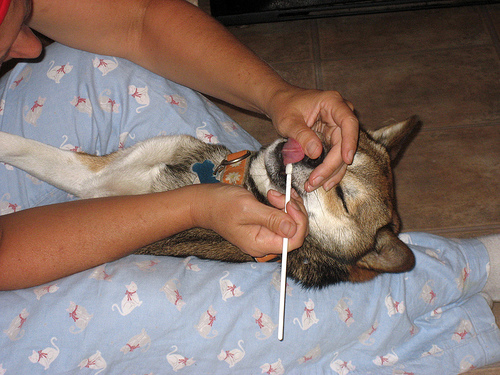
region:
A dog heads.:
[251, 94, 428, 314]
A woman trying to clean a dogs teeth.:
[267, 151, 297, 358]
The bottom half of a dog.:
[4, 128, 194, 205]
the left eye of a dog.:
[321, 170, 373, 238]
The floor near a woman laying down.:
[441, 127, 473, 177]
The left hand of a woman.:
[266, 81, 381, 206]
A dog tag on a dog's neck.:
[186, 126, 266, 208]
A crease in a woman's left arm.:
[121, 0, 174, 101]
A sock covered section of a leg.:
[481, 224, 497, 318]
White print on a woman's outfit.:
[381, 283, 421, 325]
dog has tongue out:
[280, 136, 305, 163]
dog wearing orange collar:
[220, 150, 277, 262]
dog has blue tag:
[190, 159, 215, 184]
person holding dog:
[0, 0, 499, 374]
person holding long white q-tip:
[277, 162, 293, 341]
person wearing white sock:
[476, 233, 498, 302]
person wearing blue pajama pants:
[0, 40, 498, 373]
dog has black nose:
[302, 145, 325, 167]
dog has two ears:
[356, 114, 416, 274]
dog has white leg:
[0, 129, 98, 195]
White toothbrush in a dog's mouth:
[273, 156, 293, 343]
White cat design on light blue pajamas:
[189, 299, 226, 348]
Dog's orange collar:
[221, 144, 253, 194]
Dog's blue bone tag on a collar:
[188, 156, 222, 191]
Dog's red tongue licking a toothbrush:
[280, 130, 311, 175]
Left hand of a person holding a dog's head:
[272, 60, 381, 195]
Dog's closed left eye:
[326, 162, 363, 222]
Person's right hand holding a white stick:
[211, 172, 310, 259]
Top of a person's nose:
[10, 24, 51, 68]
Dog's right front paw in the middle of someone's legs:
[0, 122, 110, 192]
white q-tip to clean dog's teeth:
[277, 158, 299, 358]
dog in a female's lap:
[9, 106, 449, 292]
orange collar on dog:
[214, 146, 253, 190]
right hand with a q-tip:
[210, 175, 320, 262]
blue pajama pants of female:
[88, 283, 275, 363]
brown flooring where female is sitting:
[344, 22, 485, 97]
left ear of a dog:
[356, 219, 418, 286]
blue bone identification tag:
[188, 158, 225, 190]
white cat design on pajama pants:
[111, 278, 148, 319]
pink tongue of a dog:
[281, 135, 308, 168]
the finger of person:
[247, 200, 296, 237]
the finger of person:
[287, 197, 304, 240]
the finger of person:
[269, 189, 299, 207]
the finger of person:
[290, 185, 307, 209]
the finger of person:
[286, 117, 321, 159]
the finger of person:
[329, 82, 359, 161]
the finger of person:
[309, 137, 339, 184]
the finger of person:
[323, 162, 346, 198]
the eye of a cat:
[330, 176, 357, 221]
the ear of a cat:
[366, 226, 417, 281]